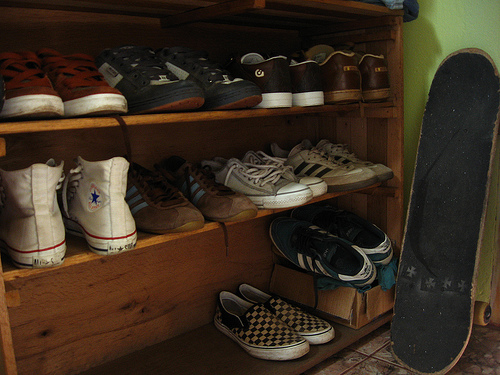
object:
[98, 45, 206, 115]
shoe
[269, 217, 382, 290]
shoe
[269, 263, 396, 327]
box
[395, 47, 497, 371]
skateboard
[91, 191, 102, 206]
logo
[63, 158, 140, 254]
shoe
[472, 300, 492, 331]
wheel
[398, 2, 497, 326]
wall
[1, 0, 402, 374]
shelf